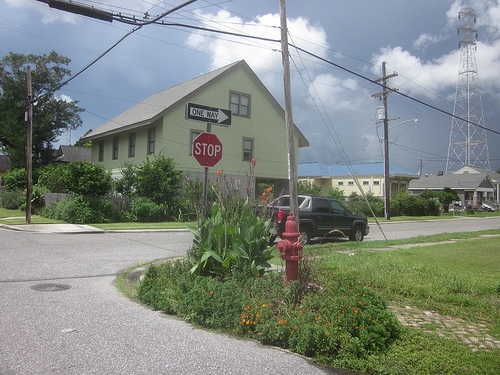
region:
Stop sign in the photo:
[177, 125, 228, 170]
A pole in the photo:
[282, 112, 304, 191]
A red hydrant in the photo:
[280, 208, 310, 278]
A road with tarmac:
[48, 249, 109, 343]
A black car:
[297, 191, 361, 244]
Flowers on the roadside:
[248, 278, 354, 344]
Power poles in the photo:
[362, 49, 422, 129]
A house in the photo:
[156, 79, 265, 189]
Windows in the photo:
[73, 128, 158, 161]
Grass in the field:
[393, 262, 470, 302]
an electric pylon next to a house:
[443, 9, 490, 174]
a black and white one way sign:
[183, 101, 230, 125]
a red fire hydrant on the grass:
[279, 210, 304, 286]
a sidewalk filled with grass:
[385, 298, 499, 358]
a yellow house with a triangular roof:
[83, 60, 310, 210]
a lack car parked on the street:
[256, 194, 368, 240]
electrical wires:
[35, 0, 499, 237]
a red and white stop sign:
[191, 132, 223, 167]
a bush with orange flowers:
[198, 275, 397, 360]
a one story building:
[300, 175, 412, 197]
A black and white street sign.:
[184, 100, 235, 130]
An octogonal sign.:
[194, 131, 224, 166]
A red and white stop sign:
[191, 128, 223, 172]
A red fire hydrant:
[279, 211, 306, 293]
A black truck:
[251, 185, 372, 243]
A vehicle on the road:
[234, 176, 381, 244]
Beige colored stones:
[297, 272, 497, 357]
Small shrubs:
[147, 245, 397, 370]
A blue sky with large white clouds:
[0, 2, 498, 169]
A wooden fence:
[37, 191, 147, 226]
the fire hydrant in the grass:
[276, 211, 304, 286]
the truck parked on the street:
[251, 192, 369, 245]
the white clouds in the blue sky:
[0, 0, 497, 176]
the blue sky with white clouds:
[0, 0, 499, 175]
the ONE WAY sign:
[185, 101, 232, 126]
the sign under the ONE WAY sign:
[191, 131, 223, 168]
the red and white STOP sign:
[191, 130, 223, 167]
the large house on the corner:
[80, 59, 310, 214]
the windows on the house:
[98, 88, 254, 162]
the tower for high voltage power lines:
[445, 6, 490, 173]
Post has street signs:
[184, 100, 232, 220]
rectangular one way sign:
[184, 99, 233, 126]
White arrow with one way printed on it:
[188, 100, 228, 124]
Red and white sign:
[190, 130, 225, 168]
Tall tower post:
[443, 5, 492, 172]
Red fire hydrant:
[275, 210, 305, 280]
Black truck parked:
[252, 193, 370, 246]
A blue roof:
[297, 160, 414, 176]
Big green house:
[77, 56, 311, 223]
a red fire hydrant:
[278, 213, 305, 281]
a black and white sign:
[184, 101, 232, 126]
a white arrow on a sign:
[188, 104, 227, 124]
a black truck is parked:
[256, 194, 369, 243]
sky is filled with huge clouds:
[0, 0, 498, 171]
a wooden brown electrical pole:
[371, 60, 399, 218]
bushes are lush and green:
[139, 254, 406, 371]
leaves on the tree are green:
[0, 51, 86, 183]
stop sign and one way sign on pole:
[167, 90, 246, 262]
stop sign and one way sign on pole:
[166, 91, 246, 268]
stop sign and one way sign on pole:
[164, 94, 250, 265]